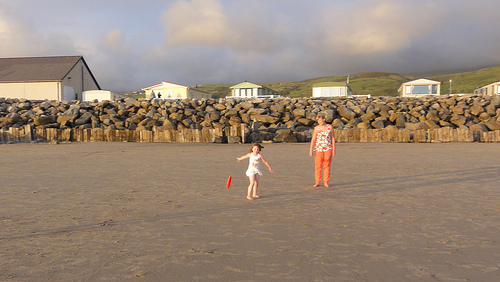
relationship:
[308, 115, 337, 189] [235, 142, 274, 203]
woman watching girl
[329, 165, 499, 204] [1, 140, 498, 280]
shadows are on sand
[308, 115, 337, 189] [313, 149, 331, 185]
woman wearing pants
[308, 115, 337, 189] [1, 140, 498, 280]
woman on sand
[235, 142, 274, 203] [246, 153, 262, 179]
girl wearing dress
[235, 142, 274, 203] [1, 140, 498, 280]
girl on sand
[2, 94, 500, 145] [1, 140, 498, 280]
seawall by sand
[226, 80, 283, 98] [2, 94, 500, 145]
buildings are by seawall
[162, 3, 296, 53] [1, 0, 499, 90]
cloud in sky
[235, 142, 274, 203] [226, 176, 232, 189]
girl throwing frisbee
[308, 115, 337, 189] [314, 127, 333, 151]
woman wearing tank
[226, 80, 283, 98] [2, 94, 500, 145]
buildings are behind seawall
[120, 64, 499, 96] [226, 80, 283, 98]
hill behind buildings